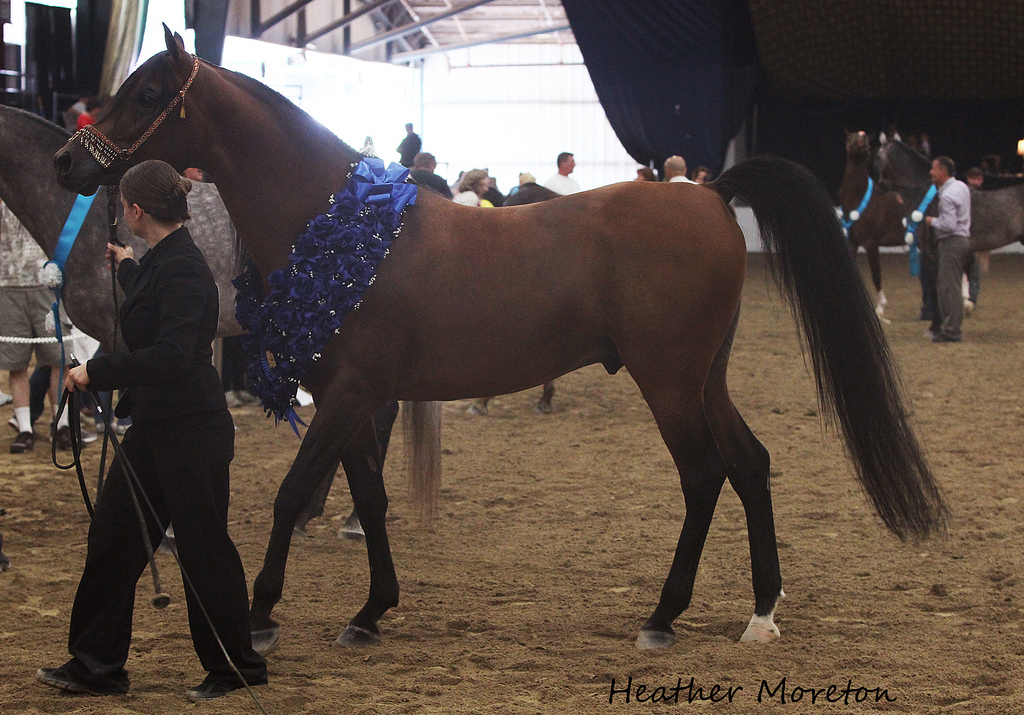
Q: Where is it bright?
A: At a rodeo.